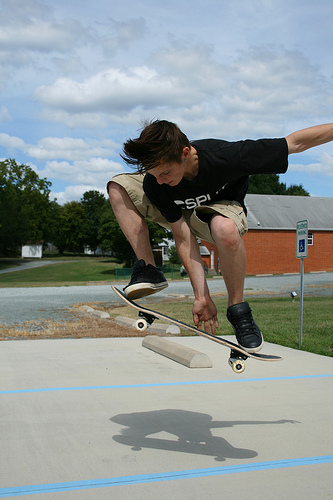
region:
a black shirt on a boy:
[140, 135, 289, 224]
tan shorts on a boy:
[106, 169, 248, 242]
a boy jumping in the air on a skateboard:
[107, 118, 331, 353]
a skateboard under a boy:
[109, 283, 283, 371]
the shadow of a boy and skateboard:
[106, 407, 302, 462]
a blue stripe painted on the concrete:
[0, 372, 331, 394]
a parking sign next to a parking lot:
[293, 218, 312, 348]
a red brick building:
[180, 195, 331, 277]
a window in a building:
[305, 230, 314, 245]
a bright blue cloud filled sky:
[1, 0, 332, 205]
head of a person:
[117, 106, 195, 195]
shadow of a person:
[114, 398, 260, 456]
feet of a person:
[110, 271, 187, 304]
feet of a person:
[227, 304, 282, 347]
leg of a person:
[103, 202, 159, 259]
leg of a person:
[203, 235, 266, 293]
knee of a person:
[94, 165, 138, 204]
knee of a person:
[205, 209, 253, 248]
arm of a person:
[161, 216, 219, 297]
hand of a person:
[180, 299, 229, 337]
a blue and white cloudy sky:
[1, 0, 332, 205]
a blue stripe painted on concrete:
[0, 371, 330, 396]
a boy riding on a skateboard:
[105, 119, 331, 354]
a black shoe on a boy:
[122, 258, 168, 299]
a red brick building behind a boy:
[179, 194, 331, 281]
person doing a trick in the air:
[110, 114, 294, 383]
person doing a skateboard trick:
[125, 124, 292, 384]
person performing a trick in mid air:
[111, 131, 268, 366]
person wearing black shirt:
[139, 129, 244, 197]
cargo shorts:
[111, 191, 265, 240]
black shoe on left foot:
[232, 301, 264, 349]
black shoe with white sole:
[228, 302, 267, 354]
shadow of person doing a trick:
[129, 397, 285, 465]